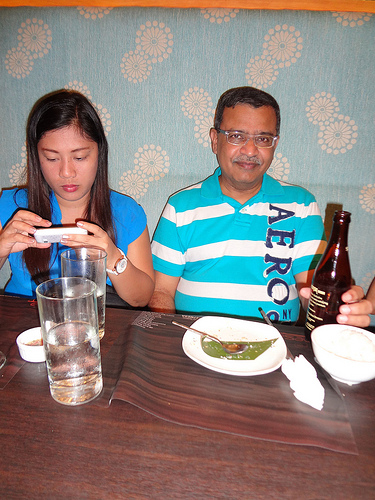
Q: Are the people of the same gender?
A: No, they are both male and female.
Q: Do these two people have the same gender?
A: No, they are both male and female.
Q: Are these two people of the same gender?
A: No, they are both male and female.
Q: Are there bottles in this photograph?
A: Yes, there is a bottle.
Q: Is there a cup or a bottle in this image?
A: Yes, there is a bottle.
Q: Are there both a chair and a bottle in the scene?
A: No, there is a bottle but no chairs.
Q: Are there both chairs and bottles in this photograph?
A: No, there is a bottle but no chairs.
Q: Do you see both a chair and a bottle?
A: No, there is a bottle but no chairs.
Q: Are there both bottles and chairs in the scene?
A: No, there is a bottle but no chairs.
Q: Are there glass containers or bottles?
A: Yes, there is a glass bottle.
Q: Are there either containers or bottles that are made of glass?
A: Yes, the bottle is made of glass.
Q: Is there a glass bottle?
A: Yes, there is a bottle that is made of glass.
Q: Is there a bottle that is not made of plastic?
A: Yes, there is a bottle that is made of glass.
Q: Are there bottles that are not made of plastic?
A: Yes, there is a bottle that is made of glass.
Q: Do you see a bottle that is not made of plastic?
A: Yes, there is a bottle that is made of glass.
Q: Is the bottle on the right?
A: Yes, the bottle is on the right of the image.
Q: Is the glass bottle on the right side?
A: Yes, the bottle is on the right of the image.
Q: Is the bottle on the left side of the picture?
A: No, the bottle is on the right of the image.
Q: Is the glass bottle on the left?
A: No, the bottle is on the right of the image.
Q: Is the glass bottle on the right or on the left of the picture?
A: The bottle is on the right of the image.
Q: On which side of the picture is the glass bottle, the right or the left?
A: The bottle is on the right of the image.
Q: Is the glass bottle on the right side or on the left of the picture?
A: The bottle is on the right of the image.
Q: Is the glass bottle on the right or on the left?
A: The bottle is on the right of the image.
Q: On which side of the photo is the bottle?
A: The bottle is on the right of the image.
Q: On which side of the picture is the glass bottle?
A: The bottle is on the right of the image.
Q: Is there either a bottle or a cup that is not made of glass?
A: No, there is a bottle but it is made of glass.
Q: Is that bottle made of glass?
A: Yes, the bottle is made of glass.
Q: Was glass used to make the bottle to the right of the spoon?
A: Yes, the bottle is made of glass.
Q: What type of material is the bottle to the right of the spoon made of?
A: The bottle is made of glass.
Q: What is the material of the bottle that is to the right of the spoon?
A: The bottle is made of glass.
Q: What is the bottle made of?
A: The bottle is made of glass.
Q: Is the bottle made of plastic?
A: No, the bottle is made of glass.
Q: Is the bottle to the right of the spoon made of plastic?
A: No, the bottle is made of glass.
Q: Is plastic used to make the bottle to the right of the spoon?
A: No, the bottle is made of glass.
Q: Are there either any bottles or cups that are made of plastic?
A: No, there is a bottle but it is made of glass.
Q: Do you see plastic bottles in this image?
A: No, there is a bottle but it is made of glass.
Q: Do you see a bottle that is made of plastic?
A: No, there is a bottle but it is made of glass.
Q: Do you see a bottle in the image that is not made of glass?
A: No, there is a bottle but it is made of glass.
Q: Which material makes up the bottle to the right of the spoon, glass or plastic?
A: The bottle is made of glass.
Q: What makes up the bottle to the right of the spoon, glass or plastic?
A: The bottle is made of glass.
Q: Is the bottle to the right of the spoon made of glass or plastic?
A: The bottle is made of glass.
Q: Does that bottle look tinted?
A: Yes, the bottle is tinted.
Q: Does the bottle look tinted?
A: Yes, the bottle is tinted.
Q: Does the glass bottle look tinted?
A: Yes, the bottle is tinted.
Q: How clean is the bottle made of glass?
A: The bottle is tinted.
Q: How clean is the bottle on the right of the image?
A: The bottle is tinted.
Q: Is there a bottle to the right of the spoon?
A: Yes, there is a bottle to the right of the spoon.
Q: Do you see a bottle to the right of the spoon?
A: Yes, there is a bottle to the right of the spoon.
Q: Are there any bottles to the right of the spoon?
A: Yes, there is a bottle to the right of the spoon.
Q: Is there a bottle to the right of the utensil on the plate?
A: Yes, there is a bottle to the right of the spoon.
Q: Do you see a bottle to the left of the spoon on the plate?
A: No, the bottle is to the right of the spoon.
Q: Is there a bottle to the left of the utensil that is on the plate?
A: No, the bottle is to the right of the spoon.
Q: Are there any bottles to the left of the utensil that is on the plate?
A: No, the bottle is to the right of the spoon.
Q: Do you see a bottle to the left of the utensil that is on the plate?
A: No, the bottle is to the right of the spoon.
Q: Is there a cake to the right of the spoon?
A: No, there is a bottle to the right of the spoon.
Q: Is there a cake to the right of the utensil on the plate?
A: No, there is a bottle to the right of the spoon.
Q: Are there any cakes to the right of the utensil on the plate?
A: No, there is a bottle to the right of the spoon.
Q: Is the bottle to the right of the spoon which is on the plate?
A: Yes, the bottle is to the right of the spoon.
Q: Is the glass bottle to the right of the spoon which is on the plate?
A: Yes, the bottle is to the right of the spoon.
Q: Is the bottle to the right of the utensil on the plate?
A: Yes, the bottle is to the right of the spoon.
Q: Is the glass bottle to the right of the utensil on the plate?
A: Yes, the bottle is to the right of the spoon.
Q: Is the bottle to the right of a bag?
A: No, the bottle is to the right of the spoon.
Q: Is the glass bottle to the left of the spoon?
A: No, the bottle is to the right of the spoon.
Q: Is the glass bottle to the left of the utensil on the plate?
A: No, the bottle is to the right of the spoon.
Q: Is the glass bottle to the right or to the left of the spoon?
A: The bottle is to the right of the spoon.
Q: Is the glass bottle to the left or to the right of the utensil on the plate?
A: The bottle is to the right of the spoon.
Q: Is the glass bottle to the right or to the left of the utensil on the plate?
A: The bottle is to the right of the spoon.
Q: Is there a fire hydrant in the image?
A: No, there are no fire hydrants.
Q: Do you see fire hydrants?
A: No, there are no fire hydrants.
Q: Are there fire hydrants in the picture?
A: No, there are no fire hydrants.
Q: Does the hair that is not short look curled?
A: No, the hair is straight.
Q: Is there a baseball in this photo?
A: No, there are no baseballs.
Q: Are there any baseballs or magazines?
A: No, there are no baseballs or magazines.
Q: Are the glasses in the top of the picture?
A: Yes, the glasses are in the top of the image.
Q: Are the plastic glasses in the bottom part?
A: No, the glasses are in the top of the image.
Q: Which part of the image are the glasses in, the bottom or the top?
A: The glasses are in the top of the image.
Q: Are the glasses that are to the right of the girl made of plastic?
A: Yes, the glasses are made of plastic.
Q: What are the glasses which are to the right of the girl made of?
A: The glasses are made of plastic.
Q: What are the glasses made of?
A: The glasses are made of plastic.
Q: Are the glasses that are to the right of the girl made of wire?
A: No, the glasses are made of plastic.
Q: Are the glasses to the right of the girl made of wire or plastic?
A: The glasses are made of plastic.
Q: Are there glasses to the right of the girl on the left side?
A: Yes, there are glasses to the right of the girl.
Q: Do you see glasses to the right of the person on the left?
A: Yes, there are glasses to the right of the girl.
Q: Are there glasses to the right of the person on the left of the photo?
A: Yes, there are glasses to the right of the girl.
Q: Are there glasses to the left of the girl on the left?
A: No, the glasses are to the right of the girl.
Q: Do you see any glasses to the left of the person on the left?
A: No, the glasses are to the right of the girl.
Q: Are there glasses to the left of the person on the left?
A: No, the glasses are to the right of the girl.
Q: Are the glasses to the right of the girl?
A: Yes, the glasses are to the right of the girl.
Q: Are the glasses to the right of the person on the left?
A: Yes, the glasses are to the right of the girl.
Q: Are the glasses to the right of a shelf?
A: No, the glasses are to the right of the girl.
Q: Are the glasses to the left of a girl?
A: No, the glasses are to the right of a girl.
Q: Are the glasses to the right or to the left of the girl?
A: The glasses are to the right of the girl.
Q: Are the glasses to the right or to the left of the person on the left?
A: The glasses are to the right of the girl.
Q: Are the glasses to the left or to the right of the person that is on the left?
A: The glasses are to the right of the girl.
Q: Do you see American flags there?
A: No, there are no American flags.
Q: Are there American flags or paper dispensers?
A: No, there are no American flags or paper dispensers.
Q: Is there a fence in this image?
A: No, there are no fences.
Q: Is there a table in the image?
A: Yes, there is a table.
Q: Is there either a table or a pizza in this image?
A: Yes, there is a table.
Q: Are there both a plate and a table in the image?
A: Yes, there are both a table and a plate.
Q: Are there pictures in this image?
A: No, there are no pictures.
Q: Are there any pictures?
A: No, there are no pictures.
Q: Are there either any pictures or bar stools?
A: No, there are no pictures or bar stools.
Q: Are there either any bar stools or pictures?
A: No, there are no pictures or bar stools.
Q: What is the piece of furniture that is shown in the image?
A: The piece of furniture is a table.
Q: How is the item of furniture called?
A: The piece of furniture is a table.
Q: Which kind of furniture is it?
A: The piece of furniture is a table.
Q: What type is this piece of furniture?
A: This is a table.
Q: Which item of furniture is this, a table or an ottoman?
A: This is a table.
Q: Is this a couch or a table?
A: This is a table.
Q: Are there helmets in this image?
A: No, there are no helmets.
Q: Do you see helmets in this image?
A: No, there are no helmets.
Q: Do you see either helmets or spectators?
A: No, there are no helmets or spectators.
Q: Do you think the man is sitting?
A: Yes, the man is sitting.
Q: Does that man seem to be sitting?
A: Yes, the man is sitting.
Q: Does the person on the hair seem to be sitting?
A: Yes, the man is sitting.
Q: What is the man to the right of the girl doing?
A: The man is sitting.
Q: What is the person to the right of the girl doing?
A: The man is sitting.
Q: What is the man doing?
A: The man is sitting.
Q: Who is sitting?
A: The man is sitting.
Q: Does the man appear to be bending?
A: No, the man is sitting.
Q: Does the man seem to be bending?
A: No, the man is sitting.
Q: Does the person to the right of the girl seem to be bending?
A: No, the man is sitting.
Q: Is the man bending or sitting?
A: The man is sitting.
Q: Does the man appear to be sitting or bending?
A: The man is sitting.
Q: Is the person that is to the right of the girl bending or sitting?
A: The man is sitting.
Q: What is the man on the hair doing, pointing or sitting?
A: The man is sitting.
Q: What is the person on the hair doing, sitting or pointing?
A: The man is sitting.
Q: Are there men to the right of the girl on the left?
A: Yes, there is a man to the right of the girl.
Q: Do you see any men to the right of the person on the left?
A: Yes, there is a man to the right of the girl.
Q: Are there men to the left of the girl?
A: No, the man is to the right of the girl.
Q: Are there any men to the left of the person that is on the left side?
A: No, the man is to the right of the girl.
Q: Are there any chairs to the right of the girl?
A: No, there is a man to the right of the girl.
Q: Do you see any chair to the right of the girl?
A: No, there is a man to the right of the girl.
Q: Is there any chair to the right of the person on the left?
A: No, there is a man to the right of the girl.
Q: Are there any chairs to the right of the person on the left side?
A: No, there is a man to the right of the girl.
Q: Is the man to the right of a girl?
A: Yes, the man is to the right of a girl.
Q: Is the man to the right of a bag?
A: No, the man is to the right of a girl.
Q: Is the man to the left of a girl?
A: No, the man is to the right of a girl.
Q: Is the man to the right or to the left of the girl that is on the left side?
A: The man is to the right of the girl.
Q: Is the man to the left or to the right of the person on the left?
A: The man is to the right of the girl.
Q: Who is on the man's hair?
A: The man is on the hair.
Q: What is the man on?
A: The man is on the hair.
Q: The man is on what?
A: The man is on the hair.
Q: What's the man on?
A: The man is on the hair.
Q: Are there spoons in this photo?
A: Yes, there is a spoon.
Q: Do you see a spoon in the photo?
A: Yes, there is a spoon.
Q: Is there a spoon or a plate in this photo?
A: Yes, there is a spoon.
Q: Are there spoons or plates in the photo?
A: Yes, there is a spoon.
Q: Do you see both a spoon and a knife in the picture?
A: No, there is a spoon but no knives.